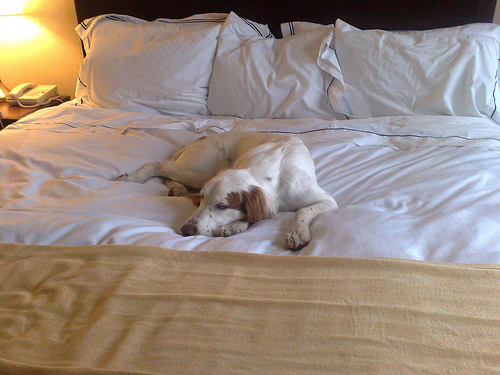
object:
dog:
[152, 126, 341, 255]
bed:
[0, 0, 500, 375]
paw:
[285, 229, 312, 251]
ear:
[243, 186, 268, 224]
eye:
[218, 203, 228, 210]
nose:
[181, 227, 197, 237]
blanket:
[0, 242, 500, 373]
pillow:
[70, 13, 228, 118]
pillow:
[208, 9, 347, 122]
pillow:
[324, 17, 500, 126]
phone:
[2, 82, 60, 107]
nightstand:
[0, 94, 71, 131]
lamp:
[0, 80, 11, 93]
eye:
[200, 193, 205, 199]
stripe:
[488, 59, 500, 120]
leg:
[116, 161, 184, 184]